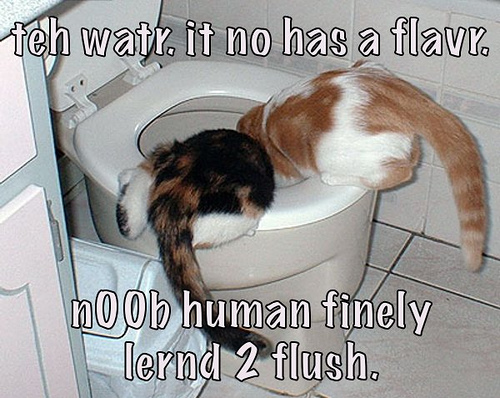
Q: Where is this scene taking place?
A: In bathroom.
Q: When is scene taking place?
A: Early morning.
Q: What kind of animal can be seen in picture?
A: Cat.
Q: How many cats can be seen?
A: 2.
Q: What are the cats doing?
A: Drinking.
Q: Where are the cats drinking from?
A: Toilet.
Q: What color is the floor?
A: White.